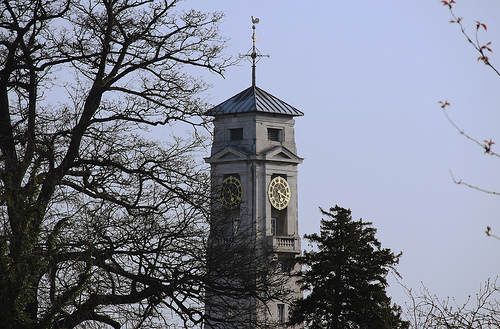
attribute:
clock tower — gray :
[195, 11, 308, 326]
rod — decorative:
[235, 13, 273, 84]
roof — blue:
[201, 84, 300, 119]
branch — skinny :
[442, 98, 499, 152]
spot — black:
[234, 81, 273, 98]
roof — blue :
[186, 82, 316, 114]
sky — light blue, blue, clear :
[0, 0, 500, 327]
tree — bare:
[0, 3, 237, 319]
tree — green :
[297, 199, 412, 327]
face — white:
[271, 175, 292, 207]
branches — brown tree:
[11, 21, 172, 276]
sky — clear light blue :
[356, 82, 408, 161]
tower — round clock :
[195, 9, 306, 299]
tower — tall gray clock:
[189, 13, 328, 324]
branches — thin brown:
[16, 13, 170, 248]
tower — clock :
[205, 17, 300, 327]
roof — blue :
[222, 86, 285, 113]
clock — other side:
[222, 165, 292, 220]